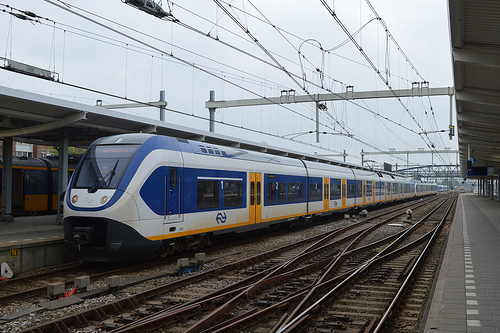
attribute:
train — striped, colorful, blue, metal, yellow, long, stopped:
[58, 127, 446, 263]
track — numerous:
[15, 190, 473, 326]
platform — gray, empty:
[6, 192, 106, 271]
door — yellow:
[165, 163, 273, 222]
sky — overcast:
[28, 6, 433, 124]